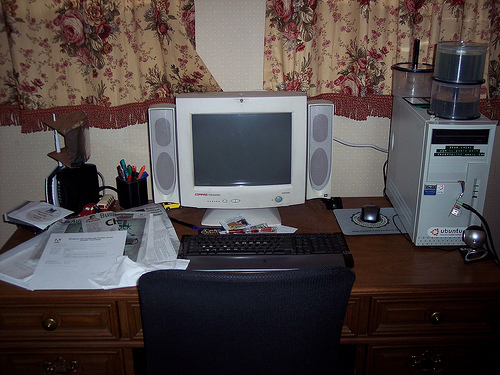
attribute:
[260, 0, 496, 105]
curtain — tan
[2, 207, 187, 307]
papers — white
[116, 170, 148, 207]
holder — black, pencil holder, pen holder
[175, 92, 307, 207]
screen — white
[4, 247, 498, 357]
desk — brown, wooden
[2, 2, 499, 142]
curtains — floral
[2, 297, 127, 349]
drawer — wooden 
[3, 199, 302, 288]
papers — assorted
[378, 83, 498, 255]
computer tower — white, silver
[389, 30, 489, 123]
cd cases — see through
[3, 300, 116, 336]
drawer — brown 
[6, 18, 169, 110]
curtain — brown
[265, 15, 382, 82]
curtain — brown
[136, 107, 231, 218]
speakers — white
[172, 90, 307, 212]
computer monitor — white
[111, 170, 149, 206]
cup — full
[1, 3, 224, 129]
blanket — brown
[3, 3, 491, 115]
flowers — red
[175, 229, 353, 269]
keyboard — black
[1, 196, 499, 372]
desk — dark, wooden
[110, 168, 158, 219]
container — black